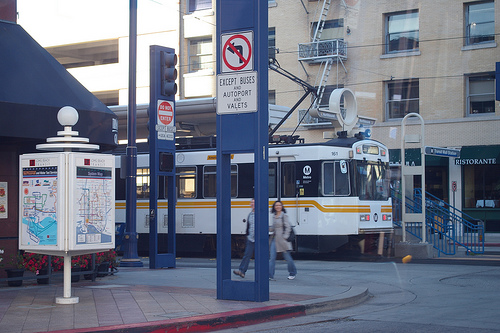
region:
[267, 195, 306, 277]
woman wearing beige jacket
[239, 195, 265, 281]
man wearing plaid shirt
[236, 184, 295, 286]
man and woman walking together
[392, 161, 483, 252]
stair rails are blue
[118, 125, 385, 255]
yellow and white tram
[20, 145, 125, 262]
map on a pole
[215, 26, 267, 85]
red and black sign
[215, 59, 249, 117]
black and white sign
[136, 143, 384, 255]
white and orange bus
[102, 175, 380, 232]
orange stripe on bus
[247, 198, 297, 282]
two people on sidewalk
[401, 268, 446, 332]
road is light grey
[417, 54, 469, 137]
tan wall on building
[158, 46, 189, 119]
black traffic light on pole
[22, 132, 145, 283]
white location directory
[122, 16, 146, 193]
black pole behind traffic light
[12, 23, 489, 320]
railcar on city intersection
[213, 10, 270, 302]
blue frame with traffic signs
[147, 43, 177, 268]
blue frame with traffic signal and traffic signs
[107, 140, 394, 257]
white railcar with yellow stripes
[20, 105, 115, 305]
elevated box displaying transportation maps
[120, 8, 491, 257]
tan building with small terraces in center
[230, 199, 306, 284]
man and woman walking in front of train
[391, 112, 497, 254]
curved metal bar in front of blue railing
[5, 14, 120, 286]
blue awning over red flowers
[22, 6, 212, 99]
light shining over parts of tan buildings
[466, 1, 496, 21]
glass window on building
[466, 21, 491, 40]
glass window on building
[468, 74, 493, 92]
glass window on building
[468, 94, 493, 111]
glass window on building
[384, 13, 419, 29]
glass window on building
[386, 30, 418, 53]
glass window on building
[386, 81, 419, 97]
glass window on building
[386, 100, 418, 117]
glass window on building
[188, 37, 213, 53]
glass window on building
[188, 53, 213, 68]
glass window on building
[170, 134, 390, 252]
Bus in the photo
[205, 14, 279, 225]
A road sign in the city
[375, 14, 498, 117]
A building in the background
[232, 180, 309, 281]
Two people walking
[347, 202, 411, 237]
A headlight on the bus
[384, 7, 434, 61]
Glass panes on the window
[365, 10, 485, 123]
Windows on the building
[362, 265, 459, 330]
Road with tarmac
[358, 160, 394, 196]
Windscreen on the bus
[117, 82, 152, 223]
A metal pole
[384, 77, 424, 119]
this is a window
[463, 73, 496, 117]
this is a window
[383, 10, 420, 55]
this is a window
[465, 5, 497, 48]
this is a window